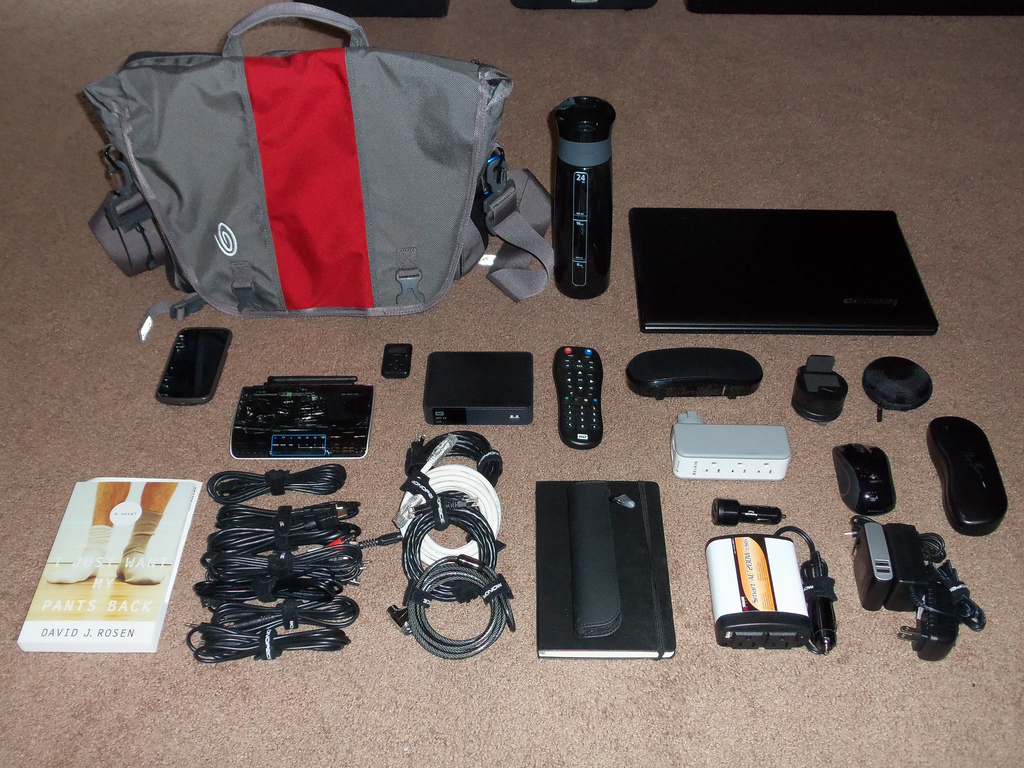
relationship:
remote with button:
[547, 342, 604, 454] [579, 342, 596, 359]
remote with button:
[547, 342, 604, 454] [552, 343, 579, 360]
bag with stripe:
[75, 7, 562, 330] [244, 47, 375, 311]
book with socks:
[15, 475, 200, 653] [40, 509, 178, 589]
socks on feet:
[40, 509, 178, 589] [44, 554, 165, 592]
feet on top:
[44, 554, 165, 592] [25, 480, 200, 640]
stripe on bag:
[241, 49, 375, 316] [75, 7, 562, 330]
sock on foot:
[114, 509, 169, 590] [111, 552, 163, 592]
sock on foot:
[54, 523, 111, 585] [41, 558, 102, 588]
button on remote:
[582, 342, 596, 358] [546, 338, 609, 449]